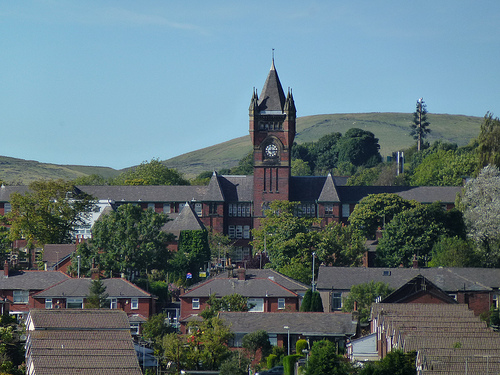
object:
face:
[265, 144, 279, 157]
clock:
[260, 135, 283, 166]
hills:
[119, 111, 500, 188]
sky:
[2, 2, 499, 171]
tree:
[407, 95, 433, 152]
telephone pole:
[76, 255, 82, 278]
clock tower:
[248, 46, 299, 258]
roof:
[248, 46, 297, 116]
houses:
[315, 260, 500, 316]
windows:
[271, 120, 285, 132]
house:
[178, 266, 299, 343]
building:
[248, 47, 296, 267]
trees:
[425, 233, 474, 269]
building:
[45, 197, 117, 240]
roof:
[180, 278, 299, 300]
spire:
[269, 46, 278, 72]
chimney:
[236, 265, 248, 281]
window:
[189, 299, 202, 311]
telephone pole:
[308, 248, 318, 288]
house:
[1, 261, 71, 310]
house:
[31, 271, 151, 337]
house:
[178, 269, 304, 373]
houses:
[415, 346, 499, 373]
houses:
[22, 306, 145, 373]